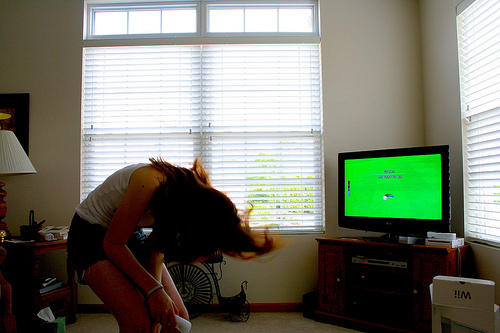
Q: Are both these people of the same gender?
A: Yes, all the people are female.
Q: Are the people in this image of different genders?
A: No, all the people are female.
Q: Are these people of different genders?
A: No, all the people are female.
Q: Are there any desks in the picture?
A: No, there are no desks.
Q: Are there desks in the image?
A: No, there are no desks.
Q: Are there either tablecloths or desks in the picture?
A: No, there are no desks or tablecloths.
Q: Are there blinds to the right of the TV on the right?
A: Yes, there are blinds to the right of the TV.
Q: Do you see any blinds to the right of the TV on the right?
A: Yes, there are blinds to the right of the TV.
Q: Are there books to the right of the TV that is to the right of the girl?
A: No, there are blinds to the right of the television.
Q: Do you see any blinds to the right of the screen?
A: Yes, there are blinds to the right of the screen.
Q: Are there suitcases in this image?
A: No, there are no suitcases.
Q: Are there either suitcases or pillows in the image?
A: No, there are no suitcases or pillows.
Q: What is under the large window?
A: The fan is under the window.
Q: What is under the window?
A: The fan is under the window.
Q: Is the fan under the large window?
A: Yes, the fan is under the window.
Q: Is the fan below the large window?
A: Yes, the fan is below the window.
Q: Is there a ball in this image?
A: No, there are no balls.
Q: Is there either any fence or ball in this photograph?
A: No, there are no balls or fences.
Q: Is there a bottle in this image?
A: No, there are no bottles.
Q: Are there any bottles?
A: No, there are no bottles.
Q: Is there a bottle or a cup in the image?
A: No, there are no bottles or cups.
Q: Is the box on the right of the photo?
A: Yes, the box is on the right of the image.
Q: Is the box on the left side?
A: No, the box is on the right of the image.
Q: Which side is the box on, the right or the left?
A: The box is on the right of the image.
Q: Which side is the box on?
A: The box is on the right of the image.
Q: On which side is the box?
A: The box is on the right of the image.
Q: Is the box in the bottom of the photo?
A: Yes, the box is in the bottom of the image.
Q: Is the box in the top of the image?
A: No, the box is in the bottom of the image.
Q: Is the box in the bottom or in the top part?
A: The box is in the bottom of the image.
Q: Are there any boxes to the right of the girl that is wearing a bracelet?
A: Yes, there is a box to the right of the girl.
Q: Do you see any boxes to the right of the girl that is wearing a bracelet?
A: Yes, there is a box to the right of the girl.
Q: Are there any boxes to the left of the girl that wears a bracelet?
A: No, the box is to the right of the girl.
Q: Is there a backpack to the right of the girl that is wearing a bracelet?
A: No, there is a box to the right of the girl.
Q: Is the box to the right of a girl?
A: Yes, the box is to the right of a girl.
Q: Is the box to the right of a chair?
A: No, the box is to the right of a girl.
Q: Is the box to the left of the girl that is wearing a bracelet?
A: No, the box is to the right of the girl.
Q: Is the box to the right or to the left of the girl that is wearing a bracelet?
A: The box is to the right of the girl.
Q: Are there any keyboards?
A: No, there are no keyboards.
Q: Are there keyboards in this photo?
A: No, there are no keyboards.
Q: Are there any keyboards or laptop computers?
A: No, there are no keyboards or laptop computers.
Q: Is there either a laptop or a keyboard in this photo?
A: No, there are no keyboards or laptops.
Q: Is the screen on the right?
A: Yes, the screen is on the right of the image.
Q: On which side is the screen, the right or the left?
A: The screen is on the right of the image.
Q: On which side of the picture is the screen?
A: The screen is on the right of the image.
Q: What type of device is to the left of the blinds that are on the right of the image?
A: The device is a screen.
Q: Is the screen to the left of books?
A: No, the screen is to the left of the blinds.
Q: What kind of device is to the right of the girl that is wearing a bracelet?
A: The device is a screen.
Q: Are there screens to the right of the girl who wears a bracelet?
A: Yes, there is a screen to the right of the girl.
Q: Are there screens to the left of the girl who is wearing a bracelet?
A: No, the screen is to the right of the girl.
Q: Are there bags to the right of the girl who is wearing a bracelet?
A: No, there is a screen to the right of the girl.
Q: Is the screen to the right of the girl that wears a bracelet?
A: Yes, the screen is to the right of the girl.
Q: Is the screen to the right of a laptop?
A: No, the screen is to the right of the girl.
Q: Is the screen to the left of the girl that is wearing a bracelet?
A: No, the screen is to the right of the girl.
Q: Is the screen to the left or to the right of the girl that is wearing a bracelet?
A: The screen is to the right of the girl.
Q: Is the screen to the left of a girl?
A: No, the screen is to the right of a girl.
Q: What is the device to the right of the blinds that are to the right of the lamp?
A: The device is a screen.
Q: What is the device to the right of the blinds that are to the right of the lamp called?
A: The device is a screen.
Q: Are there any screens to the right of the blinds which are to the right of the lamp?
A: Yes, there is a screen to the right of the blinds.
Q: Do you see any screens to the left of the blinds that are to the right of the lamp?
A: No, the screen is to the right of the blinds.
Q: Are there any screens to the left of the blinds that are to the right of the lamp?
A: No, the screen is to the right of the blinds.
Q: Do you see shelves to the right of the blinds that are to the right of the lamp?
A: No, there is a screen to the right of the blinds.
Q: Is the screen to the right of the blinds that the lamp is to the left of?
A: Yes, the screen is to the right of the blinds.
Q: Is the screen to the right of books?
A: No, the screen is to the right of the blinds.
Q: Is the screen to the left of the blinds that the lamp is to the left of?
A: No, the screen is to the right of the blinds.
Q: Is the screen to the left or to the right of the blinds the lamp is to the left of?
A: The screen is to the right of the blinds.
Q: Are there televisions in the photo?
A: Yes, there is a television.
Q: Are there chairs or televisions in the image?
A: Yes, there is a television.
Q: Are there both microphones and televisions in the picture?
A: No, there is a television but no microphones.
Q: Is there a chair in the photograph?
A: No, there are no chairs.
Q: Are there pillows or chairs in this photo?
A: No, there are no chairs or pillows.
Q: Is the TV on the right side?
A: Yes, the TV is on the right of the image.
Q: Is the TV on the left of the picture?
A: No, the TV is on the right of the image.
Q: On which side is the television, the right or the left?
A: The television is on the right of the image.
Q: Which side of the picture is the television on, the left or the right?
A: The television is on the right of the image.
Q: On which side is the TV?
A: The TV is on the right of the image.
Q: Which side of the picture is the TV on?
A: The TV is on the right of the image.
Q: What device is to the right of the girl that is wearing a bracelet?
A: The device is a television.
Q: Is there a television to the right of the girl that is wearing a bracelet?
A: Yes, there is a television to the right of the girl.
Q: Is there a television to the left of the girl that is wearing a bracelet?
A: No, the television is to the right of the girl.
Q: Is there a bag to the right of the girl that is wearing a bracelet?
A: No, there is a television to the right of the girl.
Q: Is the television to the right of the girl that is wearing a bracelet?
A: Yes, the television is to the right of the girl.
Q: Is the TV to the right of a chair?
A: No, the TV is to the right of the girl.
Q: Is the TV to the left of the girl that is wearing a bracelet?
A: No, the TV is to the right of the girl.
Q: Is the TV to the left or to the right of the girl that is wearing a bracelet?
A: The TV is to the right of the girl.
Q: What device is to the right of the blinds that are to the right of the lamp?
A: The device is a television.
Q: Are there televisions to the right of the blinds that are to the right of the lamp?
A: Yes, there is a television to the right of the blinds.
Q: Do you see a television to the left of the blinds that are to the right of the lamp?
A: No, the television is to the right of the blinds.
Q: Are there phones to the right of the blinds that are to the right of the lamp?
A: No, there is a television to the right of the blinds.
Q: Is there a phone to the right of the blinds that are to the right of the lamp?
A: No, there is a television to the right of the blinds.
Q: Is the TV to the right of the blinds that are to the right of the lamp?
A: Yes, the TV is to the right of the blinds.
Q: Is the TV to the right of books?
A: No, the TV is to the right of the blinds.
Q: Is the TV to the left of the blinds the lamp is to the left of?
A: No, the TV is to the right of the blinds.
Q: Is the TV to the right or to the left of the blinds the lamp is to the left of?
A: The TV is to the right of the blinds.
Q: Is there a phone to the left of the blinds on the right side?
A: No, there is a television to the left of the blinds.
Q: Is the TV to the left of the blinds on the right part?
A: Yes, the TV is to the left of the blinds.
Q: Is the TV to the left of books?
A: No, the TV is to the left of the blinds.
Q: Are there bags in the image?
A: No, there are no bags.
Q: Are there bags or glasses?
A: No, there are no bags or glasses.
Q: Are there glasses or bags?
A: No, there are no bags or glasses.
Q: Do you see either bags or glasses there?
A: No, there are no bags or glasses.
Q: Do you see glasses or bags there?
A: No, there are no bags or glasses.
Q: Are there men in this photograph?
A: No, there are no men.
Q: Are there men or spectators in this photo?
A: No, there are no men or spectators.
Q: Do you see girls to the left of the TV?
A: Yes, there is a girl to the left of the TV.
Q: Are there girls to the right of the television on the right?
A: No, the girl is to the left of the TV.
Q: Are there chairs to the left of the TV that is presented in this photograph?
A: No, there is a girl to the left of the TV.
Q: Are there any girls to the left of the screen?
A: Yes, there is a girl to the left of the screen.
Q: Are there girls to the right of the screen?
A: No, the girl is to the left of the screen.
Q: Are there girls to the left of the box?
A: Yes, there is a girl to the left of the box.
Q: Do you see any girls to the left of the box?
A: Yes, there is a girl to the left of the box.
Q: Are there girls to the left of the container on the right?
A: Yes, there is a girl to the left of the box.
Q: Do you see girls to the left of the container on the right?
A: Yes, there is a girl to the left of the box.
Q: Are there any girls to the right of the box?
A: No, the girl is to the left of the box.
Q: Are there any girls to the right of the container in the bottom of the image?
A: No, the girl is to the left of the box.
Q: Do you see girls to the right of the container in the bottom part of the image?
A: No, the girl is to the left of the box.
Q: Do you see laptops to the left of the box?
A: No, there is a girl to the left of the box.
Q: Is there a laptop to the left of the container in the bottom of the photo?
A: No, there is a girl to the left of the box.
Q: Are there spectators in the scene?
A: No, there are no spectators.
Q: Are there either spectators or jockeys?
A: No, there are no spectators or jockeys.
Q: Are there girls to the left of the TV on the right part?
A: Yes, there is a girl to the left of the TV.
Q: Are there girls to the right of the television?
A: No, the girl is to the left of the television.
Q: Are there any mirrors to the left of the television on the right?
A: No, there is a girl to the left of the television.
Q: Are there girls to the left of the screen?
A: Yes, there is a girl to the left of the screen.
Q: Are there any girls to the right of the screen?
A: No, the girl is to the left of the screen.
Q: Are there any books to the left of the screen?
A: No, there is a girl to the left of the screen.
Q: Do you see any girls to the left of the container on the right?
A: Yes, there is a girl to the left of the box.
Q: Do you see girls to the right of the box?
A: No, the girl is to the left of the box.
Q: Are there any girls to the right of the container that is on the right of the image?
A: No, the girl is to the left of the box.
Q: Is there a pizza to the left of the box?
A: No, there is a girl to the left of the box.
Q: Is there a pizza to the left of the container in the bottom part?
A: No, there is a girl to the left of the box.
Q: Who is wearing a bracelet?
A: The girl is wearing a bracelet.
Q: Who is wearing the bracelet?
A: The girl is wearing a bracelet.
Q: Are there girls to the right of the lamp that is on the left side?
A: Yes, there is a girl to the right of the lamp.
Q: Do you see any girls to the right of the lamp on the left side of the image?
A: Yes, there is a girl to the right of the lamp.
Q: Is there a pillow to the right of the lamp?
A: No, there is a girl to the right of the lamp.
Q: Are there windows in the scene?
A: Yes, there is a window.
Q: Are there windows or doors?
A: Yes, there is a window.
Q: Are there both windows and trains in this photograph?
A: No, there is a window but no trains.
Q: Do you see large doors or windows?
A: Yes, there is a large window.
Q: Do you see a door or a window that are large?
A: Yes, the window is large.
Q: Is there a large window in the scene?
A: Yes, there is a large window.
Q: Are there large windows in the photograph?
A: Yes, there is a large window.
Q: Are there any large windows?
A: Yes, there is a large window.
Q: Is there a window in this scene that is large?
A: Yes, there is a window that is large.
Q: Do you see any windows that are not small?
A: Yes, there is a large window.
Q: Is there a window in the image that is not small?
A: Yes, there is a large window.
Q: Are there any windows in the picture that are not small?
A: Yes, there is a large window.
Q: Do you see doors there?
A: No, there are no doors.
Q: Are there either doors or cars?
A: No, there are no doors or cars.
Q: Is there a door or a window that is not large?
A: No, there is a window but it is large.